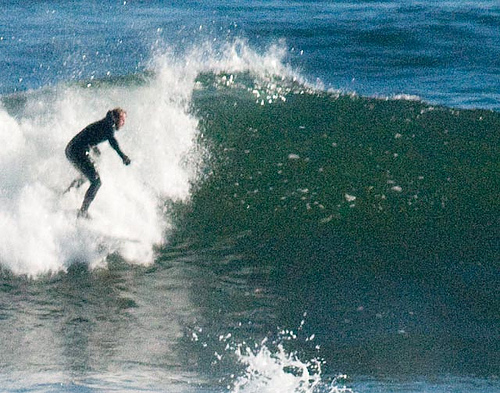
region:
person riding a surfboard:
[50, 101, 149, 227]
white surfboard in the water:
[54, 187, 158, 247]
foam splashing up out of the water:
[211, 308, 353, 391]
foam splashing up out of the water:
[140, 18, 290, 100]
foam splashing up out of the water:
[0, 73, 194, 282]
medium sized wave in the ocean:
[2, 47, 498, 283]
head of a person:
[110, 103, 129, 132]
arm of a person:
[105, 133, 131, 168]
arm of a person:
[90, 140, 106, 158]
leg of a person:
[75, 139, 109, 216]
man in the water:
[63, 97, 154, 209]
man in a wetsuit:
[74, 108, 154, 179]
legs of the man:
[56, 159, 119, 215]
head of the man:
[94, 104, 139, 145]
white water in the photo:
[149, 118, 207, 189]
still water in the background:
[341, 7, 422, 59]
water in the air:
[42, 3, 149, 82]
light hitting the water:
[17, 284, 163, 366]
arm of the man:
[107, 135, 144, 170]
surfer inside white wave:
[37, 92, 147, 237]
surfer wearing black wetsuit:
[60, 105, 135, 217]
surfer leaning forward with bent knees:
[55, 102, 130, 217]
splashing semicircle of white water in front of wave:
[205, 317, 336, 387]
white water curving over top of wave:
[160, 40, 310, 115]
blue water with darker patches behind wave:
[0, 1, 495, 106]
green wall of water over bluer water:
[202, 85, 488, 365]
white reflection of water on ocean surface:
[0, 265, 206, 386]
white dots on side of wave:
[217, 106, 422, 231]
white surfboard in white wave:
[70, 215, 147, 253]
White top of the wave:
[0, 47, 262, 279]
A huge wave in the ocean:
[15, 71, 499, 391]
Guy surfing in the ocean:
[43, 103, 135, 214]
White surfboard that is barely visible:
[43, 193, 146, 250]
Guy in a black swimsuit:
[41, 99, 136, 221]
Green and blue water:
[1, 3, 492, 391]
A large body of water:
[2, 5, 496, 387]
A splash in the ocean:
[209, 343, 329, 390]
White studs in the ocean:
[226, 123, 440, 228]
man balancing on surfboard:
[48, 105, 150, 224]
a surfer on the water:
[50, 99, 140, 227]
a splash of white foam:
[183, 315, 343, 390]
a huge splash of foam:
[2, 62, 217, 285]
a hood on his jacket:
[102, 104, 114, 127]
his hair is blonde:
[112, 106, 129, 120]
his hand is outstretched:
[105, 130, 135, 168]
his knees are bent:
[57, 139, 115, 219]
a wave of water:
[70, 27, 498, 316]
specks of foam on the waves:
[212, 102, 470, 245]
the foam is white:
[1, 94, 228, 270]